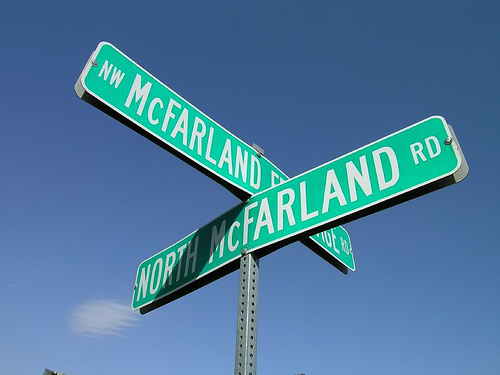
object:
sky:
[167, 15, 497, 85]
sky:
[373, 256, 430, 366]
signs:
[74, 40, 472, 316]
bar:
[234, 252, 260, 374]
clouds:
[256, 58, 332, 115]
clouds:
[295, 283, 315, 296]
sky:
[9, 106, 126, 233]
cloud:
[68, 299, 143, 339]